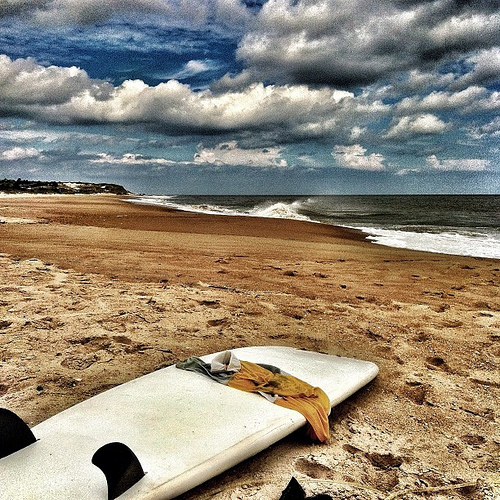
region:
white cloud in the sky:
[103, 68, 347, 152]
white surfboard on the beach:
[0, 340, 396, 496]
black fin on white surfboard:
[85, 431, 145, 496]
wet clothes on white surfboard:
[177, 341, 340, 441]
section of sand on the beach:
[53, 233, 343, 320]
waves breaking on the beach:
[337, 207, 498, 266]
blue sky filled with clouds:
[11, 9, 493, 165]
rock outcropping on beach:
[0, 175, 127, 205]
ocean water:
[381, 199, 491, 236]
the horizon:
[336, 178, 497, 213]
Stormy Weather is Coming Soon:
[3, 2, 498, 173]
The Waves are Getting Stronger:
[5, 169, 496, 276]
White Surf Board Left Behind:
[2, 336, 394, 498]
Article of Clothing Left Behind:
[162, 341, 356, 449]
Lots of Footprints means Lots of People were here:
[4, 236, 496, 494]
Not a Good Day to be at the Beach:
[3, 4, 495, 495]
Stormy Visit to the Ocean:
[6, 5, 498, 496]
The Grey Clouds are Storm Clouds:
[2, 4, 494, 156]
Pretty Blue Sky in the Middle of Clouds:
[7, 6, 257, 102]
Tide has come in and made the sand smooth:
[2, 159, 375, 257]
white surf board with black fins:
[2, 317, 387, 495]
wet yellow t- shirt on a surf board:
[176, 340, 339, 449]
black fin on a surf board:
[78, 441, 160, 497]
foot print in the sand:
[348, 438, 416, 485]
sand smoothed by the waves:
[133, 207, 224, 247]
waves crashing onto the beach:
[255, 197, 325, 237]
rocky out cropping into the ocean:
[16, 175, 130, 202]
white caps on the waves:
[251, 192, 331, 227]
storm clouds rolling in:
[213, 29, 395, 161]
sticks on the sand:
[85, 327, 184, 362]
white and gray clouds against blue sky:
[17, 10, 227, 95]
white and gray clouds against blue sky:
[198, 10, 443, 111]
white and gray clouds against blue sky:
[379, 11, 488, 181]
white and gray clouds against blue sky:
[18, 67, 234, 152]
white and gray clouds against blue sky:
[161, 90, 399, 177]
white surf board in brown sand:
[3, 339, 338, 470]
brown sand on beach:
[15, 202, 132, 265]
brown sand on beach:
[115, 222, 305, 305]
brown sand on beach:
[284, 262, 480, 339]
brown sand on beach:
[13, 271, 191, 341]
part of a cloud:
[263, 92, 316, 135]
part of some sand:
[369, 375, 422, 447]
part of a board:
[208, 405, 248, 443]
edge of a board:
[204, 441, 253, 472]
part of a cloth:
[293, 356, 338, 383]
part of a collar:
[203, 333, 233, 381]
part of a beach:
[422, 368, 467, 421]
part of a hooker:
[81, 433, 125, 465]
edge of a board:
[181, 436, 236, 479]